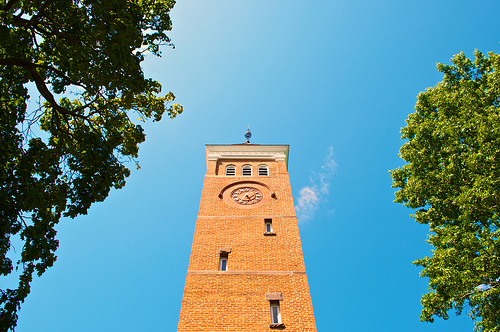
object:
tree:
[385, 47, 500, 331]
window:
[217, 257, 229, 271]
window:
[268, 305, 283, 325]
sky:
[1, 0, 500, 331]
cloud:
[291, 144, 339, 226]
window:
[225, 163, 236, 175]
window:
[257, 164, 270, 177]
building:
[175, 125, 320, 331]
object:
[241, 124, 252, 145]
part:
[274, 311, 281, 322]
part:
[272, 313, 280, 320]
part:
[327, 257, 350, 278]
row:
[224, 163, 270, 176]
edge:
[283, 159, 315, 330]